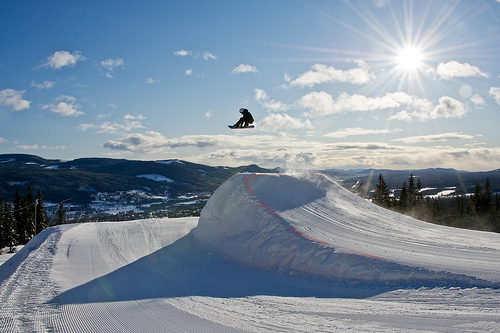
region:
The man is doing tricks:
[228, 92, 307, 149]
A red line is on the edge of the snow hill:
[239, 171, 302, 246]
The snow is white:
[67, 240, 218, 330]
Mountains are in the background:
[38, 160, 193, 202]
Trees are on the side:
[360, 168, 498, 228]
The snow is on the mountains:
[43, 141, 198, 202]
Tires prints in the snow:
[50, 276, 165, 331]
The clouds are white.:
[309, 95, 478, 168]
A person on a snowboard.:
[218, 92, 302, 161]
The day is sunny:
[335, 105, 465, 205]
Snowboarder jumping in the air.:
[220, 103, 258, 135]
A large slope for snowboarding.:
[222, 169, 413, 253]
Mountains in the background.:
[15, 149, 206, 211]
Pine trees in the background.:
[10, 188, 71, 231]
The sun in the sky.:
[372, 43, 440, 108]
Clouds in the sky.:
[283, 66, 498, 126]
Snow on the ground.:
[54, 219, 498, 324]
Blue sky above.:
[18, 36, 195, 127]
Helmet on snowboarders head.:
[229, 103, 248, 114]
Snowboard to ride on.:
[228, 122, 256, 135]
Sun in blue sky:
[371, 20, 446, 89]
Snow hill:
[220, 164, 392, 274]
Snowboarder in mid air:
[223, 98, 258, 140]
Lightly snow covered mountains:
[24, 147, 186, 202]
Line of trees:
[6, 192, 56, 234]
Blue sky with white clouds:
[31, 21, 213, 113]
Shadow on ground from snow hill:
[67, 257, 197, 322]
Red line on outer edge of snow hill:
[238, 172, 265, 202]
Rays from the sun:
[363, 7, 456, 36]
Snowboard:
[228, 122, 261, 132]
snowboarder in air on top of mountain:
[68, 71, 433, 281]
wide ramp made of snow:
[191, 155, 491, 295]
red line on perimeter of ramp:
[235, 165, 390, 275]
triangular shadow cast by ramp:
[35, 215, 381, 320]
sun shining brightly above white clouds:
[280, 15, 471, 155]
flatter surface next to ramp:
[25, 156, 310, 322]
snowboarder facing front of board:
[215, 82, 265, 138]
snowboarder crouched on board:
[220, 92, 265, 138]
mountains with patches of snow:
[26, 137, 221, 229]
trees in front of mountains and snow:
[342, 155, 493, 225]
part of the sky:
[230, 19, 277, 51]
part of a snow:
[271, 280, 320, 312]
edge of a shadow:
[161, 280, 201, 309]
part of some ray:
[350, 150, 389, 198]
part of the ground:
[340, 205, 388, 243]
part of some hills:
[127, 157, 177, 199]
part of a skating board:
[241, 122, 256, 138]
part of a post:
[23, 200, 41, 232]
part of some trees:
[19, 187, 49, 221]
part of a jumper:
[243, 107, 257, 122]